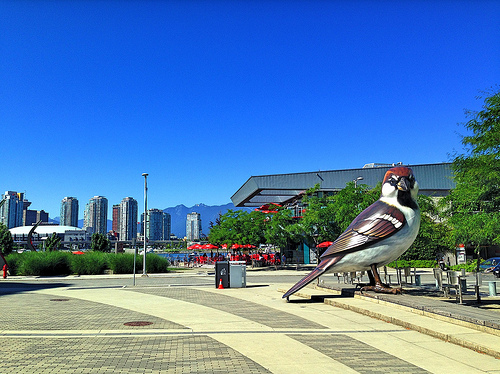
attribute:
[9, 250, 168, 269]
bushes — green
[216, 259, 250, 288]
two — black, white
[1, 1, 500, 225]
clear — blue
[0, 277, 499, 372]
cement — gray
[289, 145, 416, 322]
bird — large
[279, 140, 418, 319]
bird — brown, white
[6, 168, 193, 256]
buildings — tall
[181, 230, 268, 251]
umbrellas — red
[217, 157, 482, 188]
roof — grey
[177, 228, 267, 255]
umbrellas — red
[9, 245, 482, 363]
pathway — stone, cement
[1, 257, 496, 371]
walkway — striped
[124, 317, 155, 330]
grate — brown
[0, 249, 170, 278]
shrubbery — dark green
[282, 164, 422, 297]
statue — large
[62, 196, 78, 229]
building — high-rise